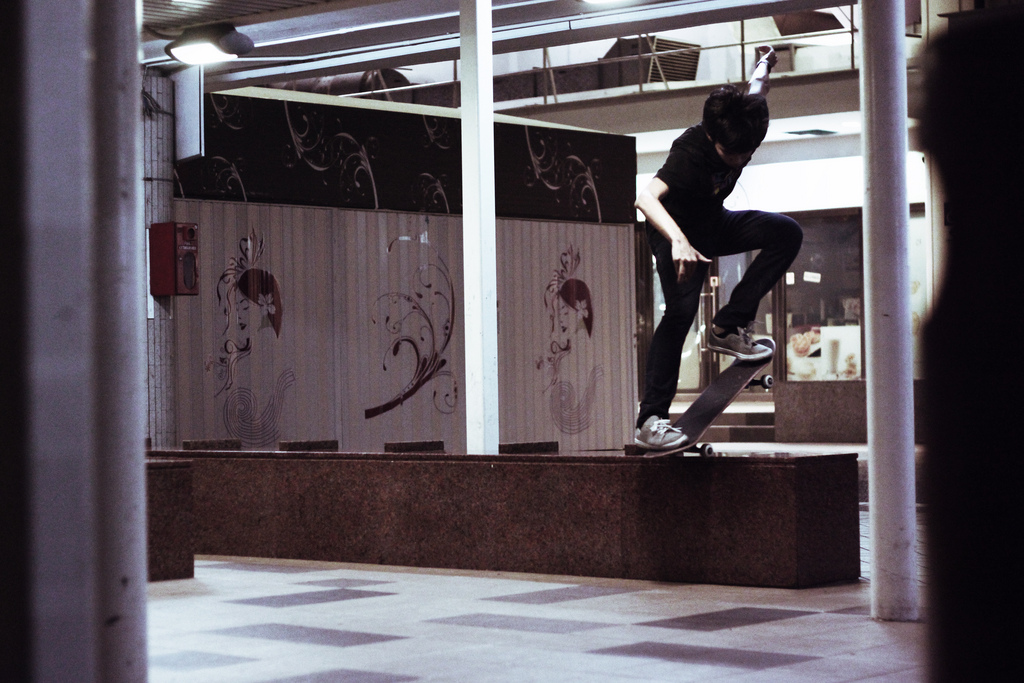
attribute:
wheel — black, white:
[659, 430, 722, 465]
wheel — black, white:
[743, 370, 778, 392]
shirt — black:
[661, 124, 748, 241]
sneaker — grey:
[620, 404, 692, 463]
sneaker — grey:
[689, 307, 793, 381]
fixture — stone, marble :
[167, 420, 874, 591]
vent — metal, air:
[586, 28, 718, 83]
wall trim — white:
[213, 78, 609, 145]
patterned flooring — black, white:
[176, 571, 831, 678]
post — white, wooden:
[446, 0, 511, 456]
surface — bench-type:
[157, 437, 879, 589]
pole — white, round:
[850, 9, 933, 632]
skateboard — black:
[693, 329, 776, 440]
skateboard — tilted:
[682, 326, 784, 433]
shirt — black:
[647, 80, 781, 227]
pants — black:
[647, 210, 808, 412]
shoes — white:
[641, 326, 748, 461]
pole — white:
[842, 9, 925, 619]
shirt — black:
[651, 87, 775, 232]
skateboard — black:
[673, 322, 795, 465]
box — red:
[144, 205, 209, 316]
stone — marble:
[139, 443, 868, 586]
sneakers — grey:
[628, 329, 793, 455]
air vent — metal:
[582, 24, 710, 98]